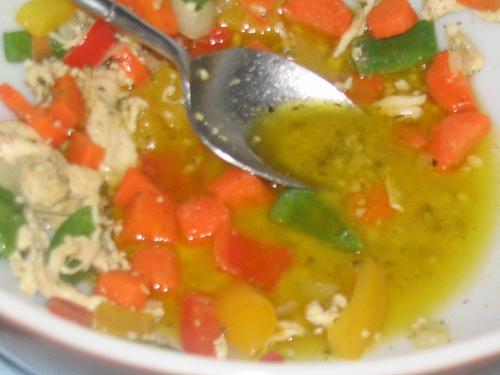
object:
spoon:
[66, 0, 371, 190]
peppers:
[350, 16, 438, 79]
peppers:
[271, 182, 364, 257]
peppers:
[3, 28, 78, 63]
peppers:
[41, 201, 106, 284]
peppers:
[1, 187, 26, 264]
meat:
[440, 22, 483, 77]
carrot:
[202, 166, 281, 213]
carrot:
[110, 163, 175, 202]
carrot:
[170, 190, 242, 243]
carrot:
[210, 223, 297, 289]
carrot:
[132, 245, 189, 299]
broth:
[101, 0, 498, 359]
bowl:
[0, 0, 500, 374]